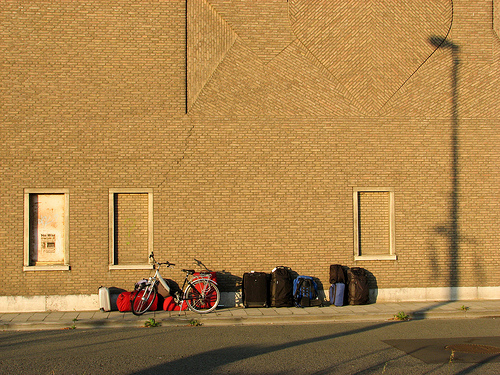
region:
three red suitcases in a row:
[116, 268, 223, 310]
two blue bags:
[291, 272, 347, 305]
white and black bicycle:
[128, 249, 224, 317]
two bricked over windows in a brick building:
[101, 180, 400, 272]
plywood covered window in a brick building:
[18, 183, 72, 275]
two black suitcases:
[239, 261, 291, 313]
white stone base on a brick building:
[1, 278, 498, 316]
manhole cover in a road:
[445, 338, 499, 360]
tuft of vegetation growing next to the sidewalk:
[391, 308, 413, 322]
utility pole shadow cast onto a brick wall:
[428, 94, 489, 309]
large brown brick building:
[7, 8, 490, 268]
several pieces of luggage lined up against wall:
[238, 263, 373, 308]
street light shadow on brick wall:
[424, 29, 468, 320]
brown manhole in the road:
[442, 340, 499, 362]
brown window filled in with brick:
[107, 186, 155, 269]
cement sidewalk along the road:
[0, 303, 498, 328]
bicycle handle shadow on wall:
[189, 256, 213, 276]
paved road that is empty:
[2, 331, 488, 373]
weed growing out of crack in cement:
[389, 309, 411, 324]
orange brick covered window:
[352, 183, 402, 266]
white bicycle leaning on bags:
[131, 253, 222, 312]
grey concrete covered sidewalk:
[2, 300, 499, 327]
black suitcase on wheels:
[242, 271, 272, 307]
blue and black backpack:
[292, 269, 326, 310]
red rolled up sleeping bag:
[118, 291, 160, 312]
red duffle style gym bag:
[166, 296, 208, 313]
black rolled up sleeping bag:
[347, 264, 371, 309]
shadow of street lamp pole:
[428, 31, 475, 325]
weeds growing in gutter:
[141, 316, 158, 330]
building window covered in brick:
[347, 183, 402, 269]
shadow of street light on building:
[424, 25, 473, 160]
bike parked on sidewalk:
[129, 252, 218, 319]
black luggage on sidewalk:
[232, 259, 299, 318]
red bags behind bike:
[116, 269, 215, 314]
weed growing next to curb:
[384, 304, 419, 329]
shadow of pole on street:
[292, 323, 364, 353]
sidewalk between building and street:
[332, 300, 439, 323]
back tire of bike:
[181, 273, 226, 315]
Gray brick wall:
[70, 77, 352, 248]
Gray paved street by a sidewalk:
[122, 326, 196, 374]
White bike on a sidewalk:
[126, 251, 226, 323]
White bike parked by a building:
[132, 248, 225, 317]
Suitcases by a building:
[231, 243, 383, 310]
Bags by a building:
[90, 281, 227, 325]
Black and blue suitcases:
[243, 243, 362, 318]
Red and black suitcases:
[96, 282, 222, 316]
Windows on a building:
[26, 178, 184, 292]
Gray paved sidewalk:
[235, 291, 388, 322]